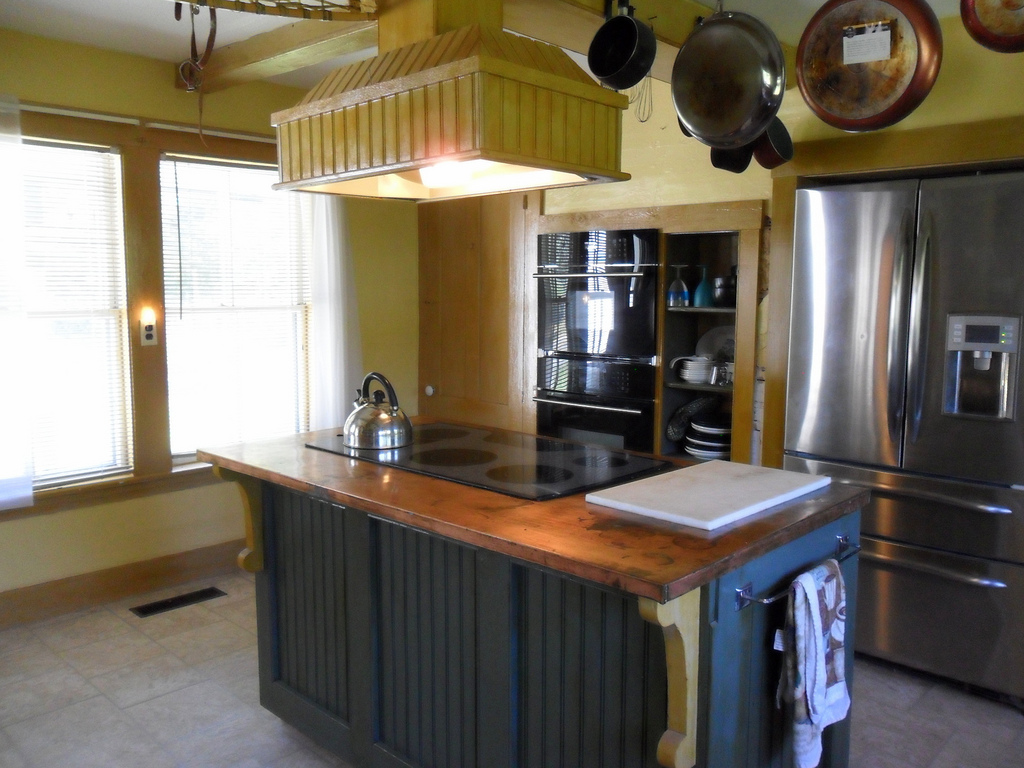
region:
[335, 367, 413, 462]
Silver tea-pot with a black handle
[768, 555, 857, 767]
towel hanging on a towel bar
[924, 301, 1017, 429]
dispenser in the front of the refrigerator door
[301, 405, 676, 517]
glass-top cooking stove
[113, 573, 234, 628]
air duct in the floor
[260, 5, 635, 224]
hood hanging above the cook stove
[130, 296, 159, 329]
Nightlight between 2 windows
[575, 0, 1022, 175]
group of pans hanging from the ceiling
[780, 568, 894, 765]
white towel hanging on silver kitchen rack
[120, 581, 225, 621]
dark colored vent located in the floor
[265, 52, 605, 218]
yellow colored light fixture in kitchen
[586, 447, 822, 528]
white colored cutting board in kitchen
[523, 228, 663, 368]
top black oven with silver handles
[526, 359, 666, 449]
black lower oven with silver handle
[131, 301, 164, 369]
small light plugged into outlet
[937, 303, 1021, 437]
icemaker located in stainless steel refrigerator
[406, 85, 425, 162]
ceiling light has a wood panel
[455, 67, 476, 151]
ceiling light has a wood panel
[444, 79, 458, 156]
ceiling light has a wood panel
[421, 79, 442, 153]
ceiling light has a wood panel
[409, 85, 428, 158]
ceiling light has a wood panel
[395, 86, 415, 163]
ceiling light has a wood panel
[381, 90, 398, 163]
ceiling light has a wood panel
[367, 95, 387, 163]
ceiling light has a wood panel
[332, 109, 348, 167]
ceiling light has a wood panel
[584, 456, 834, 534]
A big and white chopping board.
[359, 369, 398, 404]
A plain black handle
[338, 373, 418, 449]
A stainless steel kettle.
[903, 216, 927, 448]
A long and silver handle.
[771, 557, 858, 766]
A white with brown designs towel.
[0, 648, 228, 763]
Brown tiles on the floor.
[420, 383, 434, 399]
A wsmall and white doorknob.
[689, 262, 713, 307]
A blue wine glass downside up.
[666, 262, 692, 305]
A clear glass with blue dash.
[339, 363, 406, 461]
the kettle is silver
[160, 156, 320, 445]
window on the wall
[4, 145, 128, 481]
window on the wall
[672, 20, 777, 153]
a pan is hanging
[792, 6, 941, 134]
a pan is hanging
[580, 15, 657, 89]
a pan is hanging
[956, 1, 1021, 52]
a pan is hanging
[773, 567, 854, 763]
a towel is hanging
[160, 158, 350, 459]
a large kitchen window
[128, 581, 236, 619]
a long black floor vent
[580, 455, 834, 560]
a long white cutting board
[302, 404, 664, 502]
a flat stove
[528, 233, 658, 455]
a large black wall oven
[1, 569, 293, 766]
white tile kitchen floor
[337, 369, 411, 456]
a gray tea kettle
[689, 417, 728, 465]
a stack of plates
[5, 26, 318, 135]
a yellow painted wall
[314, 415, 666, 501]
an induction stove top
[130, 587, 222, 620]
a heating vent in the ground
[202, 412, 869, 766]
an island counter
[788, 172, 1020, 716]
a stainless steel refrigerator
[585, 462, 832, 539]
a white chopping board on a counter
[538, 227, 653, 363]
an oven door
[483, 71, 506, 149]
A small plank of wood.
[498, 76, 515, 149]
A small plank of wood.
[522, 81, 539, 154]
A small plank of wood.